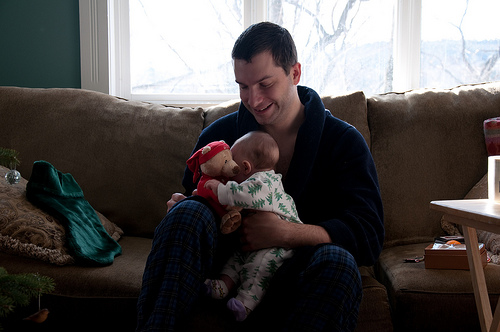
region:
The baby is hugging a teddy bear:
[188, 122, 336, 311]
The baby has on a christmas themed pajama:
[200, 171, 283, 328]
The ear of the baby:
[239, 155, 260, 175]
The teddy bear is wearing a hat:
[180, 126, 220, 158]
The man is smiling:
[221, 8, 343, 142]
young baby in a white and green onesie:
[199, 128, 303, 320]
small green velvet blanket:
[21, 156, 126, 264]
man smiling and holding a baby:
[133, 20, 387, 330]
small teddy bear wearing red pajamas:
[181, 136, 251, 238]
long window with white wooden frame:
[78, 0, 499, 106]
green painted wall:
[0, 0, 84, 90]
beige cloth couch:
[1, 81, 498, 330]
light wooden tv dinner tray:
[429, 198, 499, 328]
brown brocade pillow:
[1, 167, 126, 267]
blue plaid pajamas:
[134, 85, 386, 330]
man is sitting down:
[0, 10, 499, 327]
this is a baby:
[197, 117, 308, 317]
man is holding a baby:
[99, 0, 401, 326]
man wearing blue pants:
[138, 178, 380, 330]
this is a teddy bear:
[175, 128, 245, 206]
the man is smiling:
[219, 0, 314, 130]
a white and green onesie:
[208, 152, 316, 328]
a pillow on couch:
[46, 147, 121, 286]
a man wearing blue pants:
[279, 205, 344, 330]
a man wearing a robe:
[177, 70, 439, 328]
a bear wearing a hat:
[162, 138, 306, 244]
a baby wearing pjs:
[248, 126, 363, 326]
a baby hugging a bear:
[161, 126, 368, 302]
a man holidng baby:
[186, 32, 361, 299]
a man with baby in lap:
[219, 53, 357, 256]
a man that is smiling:
[204, 28, 360, 248]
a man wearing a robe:
[232, 37, 390, 303]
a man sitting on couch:
[176, 0, 429, 330]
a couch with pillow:
[0, 133, 144, 330]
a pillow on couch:
[9, 127, 141, 312]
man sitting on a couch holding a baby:
[0, 20, 495, 325]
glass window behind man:
[79, 0, 498, 329]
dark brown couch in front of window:
[1, 1, 496, 330]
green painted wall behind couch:
[0, 1, 498, 330]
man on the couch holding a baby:
[136, 20, 386, 328]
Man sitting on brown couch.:
[136, 20, 385, 329]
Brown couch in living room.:
[0, 80, 499, 330]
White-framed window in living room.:
[77, 0, 497, 108]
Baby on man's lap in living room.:
[201, 130, 301, 318]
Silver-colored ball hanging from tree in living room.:
[5, 168, 20, 183]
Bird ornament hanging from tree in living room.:
[20, 305, 46, 321]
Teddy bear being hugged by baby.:
[185, 137, 241, 232]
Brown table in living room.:
[430, 195, 497, 328]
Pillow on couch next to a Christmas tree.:
[0, 165, 122, 262]